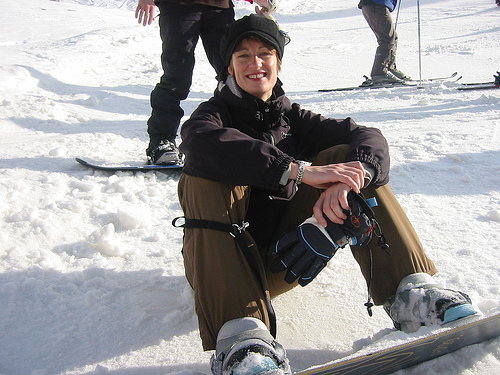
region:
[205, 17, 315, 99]
a woman wearing a black hat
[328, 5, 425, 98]
a person wearing skis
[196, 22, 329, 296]
a woman holding a pair of gloves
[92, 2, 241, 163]
a person wearing black pants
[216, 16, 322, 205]
a woman wearing a watch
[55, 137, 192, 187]
a snow board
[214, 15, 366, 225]
a woman holding her wrist with her hand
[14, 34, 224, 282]
ground covered in snow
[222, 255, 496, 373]
a woman's feet has snow on them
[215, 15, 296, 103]
a woman smiling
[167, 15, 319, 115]
smiling woman in black cap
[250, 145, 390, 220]
one hand holding wrist of other hand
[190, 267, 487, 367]
snow-covered boots attached to snowboard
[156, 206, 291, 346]
strap connected under knee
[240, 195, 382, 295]
fingers curled around glove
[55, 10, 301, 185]
person standing behind snowboarder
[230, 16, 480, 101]
skier to right of snowboarder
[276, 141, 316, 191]
silver watch on wrist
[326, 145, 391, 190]
elastic closure on sleeve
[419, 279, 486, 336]
blue tips of boots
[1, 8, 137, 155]
a big load of snow on the ground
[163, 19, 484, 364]
a woman sitting on the snowy ground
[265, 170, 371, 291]
a glove in the woman's hand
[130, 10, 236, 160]
the long dark pants of a man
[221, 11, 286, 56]
the hat on the woman's head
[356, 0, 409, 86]
a person standing on the skiis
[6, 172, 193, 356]
even more snow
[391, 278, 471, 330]
the shoe on the woman's foot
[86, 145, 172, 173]
the snowboard on the ground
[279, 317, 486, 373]
the snowboard on the womans feet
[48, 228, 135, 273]
deep indent in white snow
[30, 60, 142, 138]
skier's shadow in snow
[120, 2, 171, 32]
white fingers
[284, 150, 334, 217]
large silver watch on woman's hand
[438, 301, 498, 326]
blue tip of sneakers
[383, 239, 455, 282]
wrinkles in brown pants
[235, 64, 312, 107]
wide grin on woman's face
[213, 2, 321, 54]
black cap on woman's head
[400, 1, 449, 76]
black skinny ski poles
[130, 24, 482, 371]
woman skier sitting on snow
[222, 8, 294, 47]
The womans black hat.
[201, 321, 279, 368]
The womans right ski boot.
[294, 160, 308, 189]
The silver bracelet on the womans wrist.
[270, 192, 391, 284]
The womans glove.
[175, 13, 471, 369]
A womans sitting on the ground in the snow.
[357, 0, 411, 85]
A man with tan pants.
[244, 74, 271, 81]
The womans mouth.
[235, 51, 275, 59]
The womans eyes.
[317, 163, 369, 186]
The womans right hand.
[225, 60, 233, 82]
The womans right ear.